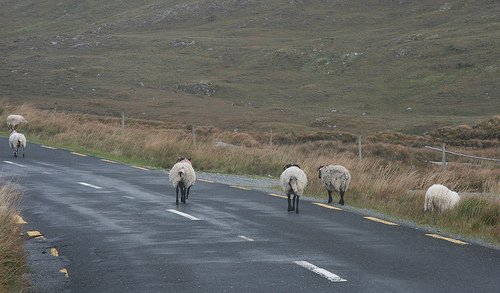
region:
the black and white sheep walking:
[6, 126, 28, 160]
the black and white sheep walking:
[170, 153, 197, 203]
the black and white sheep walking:
[279, 161, 307, 212]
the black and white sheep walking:
[315, 161, 352, 207]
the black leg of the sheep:
[285, 191, 292, 213]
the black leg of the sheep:
[290, 192, 295, 209]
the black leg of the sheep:
[294, 193, 302, 215]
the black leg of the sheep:
[172, 186, 178, 204]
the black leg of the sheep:
[180, 182, 186, 203]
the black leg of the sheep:
[185, 182, 190, 199]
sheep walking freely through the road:
[134, 134, 469, 239]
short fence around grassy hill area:
[104, 96, 211, 148]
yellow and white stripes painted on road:
[12, 167, 141, 255]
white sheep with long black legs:
[272, 155, 322, 218]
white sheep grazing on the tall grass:
[410, 174, 481, 235]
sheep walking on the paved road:
[3, 108, 50, 167]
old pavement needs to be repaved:
[58, 196, 140, 264]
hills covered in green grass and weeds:
[20, 6, 475, 111]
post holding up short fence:
[107, 101, 131, 142]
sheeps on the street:
[2, 108, 464, 218]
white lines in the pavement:
[3, 155, 349, 290]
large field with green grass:
[5, 1, 499, 233]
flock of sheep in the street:
[9, 113, 464, 232]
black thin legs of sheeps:
[6, 108, 463, 222]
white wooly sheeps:
[5, 109, 466, 233]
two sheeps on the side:
[6, 114, 468, 221]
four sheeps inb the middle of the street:
[12, 126, 354, 221]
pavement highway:
[3, 134, 499, 290]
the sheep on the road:
[160, 152, 219, 209]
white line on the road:
[282, 248, 357, 290]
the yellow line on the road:
[360, 211, 404, 230]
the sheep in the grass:
[395, 180, 472, 220]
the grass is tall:
[334, 147, 426, 222]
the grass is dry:
[359, 161, 411, 207]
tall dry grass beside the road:
[352, 153, 417, 213]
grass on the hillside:
[16, 8, 490, 133]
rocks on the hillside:
[36, 16, 420, 105]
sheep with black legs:
[172, 181, 192, 207]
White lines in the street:
[98, 184, 309, 282]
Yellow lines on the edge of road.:
[316, 192, 478, 271]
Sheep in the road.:
[153, 139, 465, 234]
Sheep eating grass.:
[420, 168, 462, 227]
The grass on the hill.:
[101, 14, 451, 145]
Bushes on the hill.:
[297, 117, 459, 158]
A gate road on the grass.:
[391, 137, 483, 182]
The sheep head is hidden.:
[419, 173, 464, 219]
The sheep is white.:
[148, 149, 210, 200]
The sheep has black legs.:
[270, 189, 314, 219]